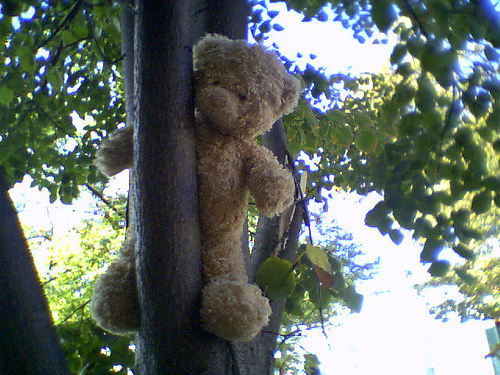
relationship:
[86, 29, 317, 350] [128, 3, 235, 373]
teddy bear in tree branch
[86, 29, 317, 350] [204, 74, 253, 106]
teddy bear has eyes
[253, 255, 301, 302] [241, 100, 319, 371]
leaf on tree branch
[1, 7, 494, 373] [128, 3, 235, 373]
tree has tree branch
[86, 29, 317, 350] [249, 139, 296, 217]
teddy bear has left arm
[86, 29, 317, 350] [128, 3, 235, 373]
teddy bear sitting in tree branch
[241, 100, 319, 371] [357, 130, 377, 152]
tree branch has leaf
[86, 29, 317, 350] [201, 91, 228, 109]
teddy bear has nose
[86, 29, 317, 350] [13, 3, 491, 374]
teddy bear in shade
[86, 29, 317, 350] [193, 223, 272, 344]
teddy bear has leg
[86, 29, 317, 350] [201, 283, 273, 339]
teddy bear has foot